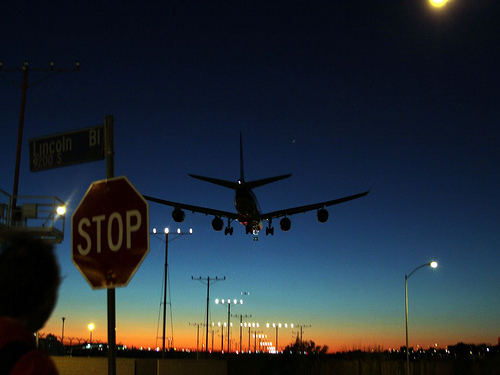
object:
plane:
[133, 131, 373, 241]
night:
[236, 19, 389, 112]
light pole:
[398, 270, 417, 355]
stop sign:
[70, 180, 150, 290]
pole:
[94, 277, 127, 374]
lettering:
[73, 211, 143, 254]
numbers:
[26, 153, 58, 173]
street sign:
[26, 130, 106, 174]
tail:
[190, 129, 295, 196]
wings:
[143, 185, 374, 218]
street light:
[422, 257, 439, 270]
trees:
[280, 331, 329, 353]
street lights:
[146, 223, 296, 360]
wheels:
[211, 217, 293, 242]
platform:
[4, 193, 69, 244]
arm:
[407, 261, 429, 282]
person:
[5, 240, 63, 375]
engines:
[170, 204, 329, 231]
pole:
[0, 60, 44, 196]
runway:
[204, 333, 350, 362]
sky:
[62, 16, 419, 124]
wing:
[260, 189, 370, 217]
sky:
[320, 302, 489, 348]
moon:
[423, 1, 449, 14]